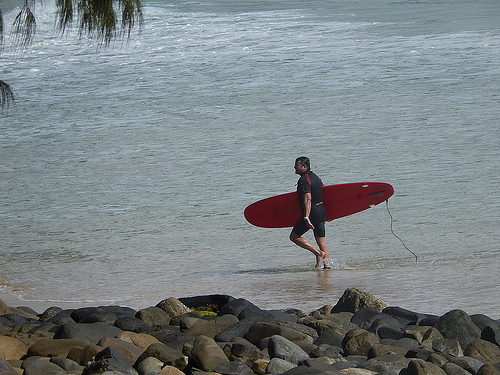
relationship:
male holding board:
[289, 156, 331, 271] [241, 183, 395, 228]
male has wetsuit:
[289, 156, 331, 271] [289, 170, 328, 237]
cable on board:
[382, 198, 421, 260] [240, 180, 391, 229]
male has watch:
[289, 156, 331, 271] [302, 217, 308, 222]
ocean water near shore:
[0, 1, 497, 318] [1, 292, 497, 372]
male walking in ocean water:
[289, 156, 331, 271] [0, 1, 497, 318]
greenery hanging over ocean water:
[2, 4, 142, 108] [0, 1, 497, 318]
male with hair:
[289, 156, 331, 271] [292, 154, 312, 167]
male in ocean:
[289, 156, 331, 271] [122, 86, 154, 120]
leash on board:
[385, 198, 417, 262] [242, 181, 395, 228]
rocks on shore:
[2, 293, 494, 371] [4, 277, 496, 320]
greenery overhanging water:
[0, 0, 143, 109] [0, 0, 498, 319]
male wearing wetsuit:
[289, 156, 331, 271] [291, 168, 326, 238]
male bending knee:
[287, 154, 334, 271] [288, 225, 305, 245]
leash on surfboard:
[377, 198, 427, 263] [239, 185, 411, 234]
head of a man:
[292, 156, 312, 177] [288, 153, 331, 283]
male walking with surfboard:
[289, 156, 331, 271] [241, 178, 399, 227]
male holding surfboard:
[289, 156, 331, 271] [242, 184, 398, 218]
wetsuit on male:
[290, 174, 328, 241] [289, 156, 331, 271]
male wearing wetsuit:
[289, 156, 331, 271] [293, 176, 331, 239]